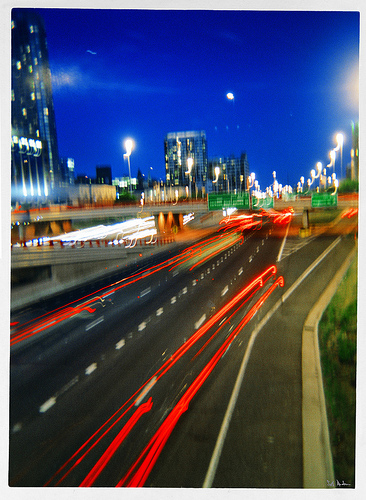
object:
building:
[164, 129, 209, 196]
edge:
[299, 241, 356, 491]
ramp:
[10, 239, 174, 309]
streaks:
[43, 264, 285, 487]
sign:
[208, 191, 251, 211]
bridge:
[18, 202, 360, 247]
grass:
[157, 122, 212, 195]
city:
[8, 9, 355, 488]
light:
[8, 9, 359, 489]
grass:
[317, 249, 357, 488]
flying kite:
[214, 90, 364, 176]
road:
[8, 210, 355, 487]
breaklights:
[152, 329, 224, 426]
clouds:
[45, 9, 360, 190]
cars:
[9, 197, 355, 491]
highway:
[8, 194, 360, 490]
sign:
[311, 192, 338, 209]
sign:
[252, 194, 274, 211]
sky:
[42, 11, 360, 193]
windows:
[12, 57, 44, 132]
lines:
[38, 307, 157, 414]